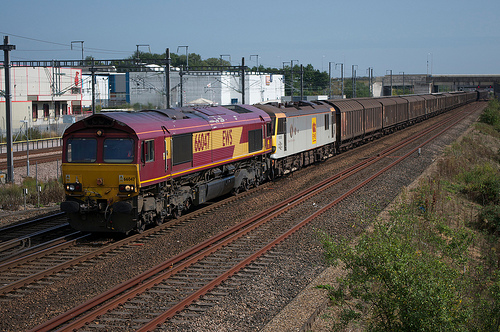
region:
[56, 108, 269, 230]
dark red train engine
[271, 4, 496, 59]
clear afternoon sky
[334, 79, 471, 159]
long line of cargo trains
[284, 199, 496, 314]
foliage bounding the tracks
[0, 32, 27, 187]
telephone poles near the trains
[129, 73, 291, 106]
white buildings in background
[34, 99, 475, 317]
rusty train tracks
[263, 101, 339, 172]
grey secondary train engine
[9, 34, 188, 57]
telephone wires running overhead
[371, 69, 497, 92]
bridge over the tracks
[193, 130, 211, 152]
numbers on the side of a train "66047"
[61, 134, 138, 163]
two train engine windows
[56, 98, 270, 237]
a red and yellow train engine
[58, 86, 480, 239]
a train on the train tracks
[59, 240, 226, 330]
a section of railroad tracks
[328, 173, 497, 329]
bushes on the side of train tracks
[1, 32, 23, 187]
power line pole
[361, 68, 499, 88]
An overpass over train tracks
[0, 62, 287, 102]
two buildings in next to train tracks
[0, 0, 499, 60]
a clear blue sky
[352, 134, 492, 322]
trees near railroad tracks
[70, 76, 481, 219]
long cargo train with many cars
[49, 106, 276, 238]
red first train engine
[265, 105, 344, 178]
grey second train engine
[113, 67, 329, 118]
white buildings in background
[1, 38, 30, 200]
telephone poles with wires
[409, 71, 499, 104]
bridge running over tracks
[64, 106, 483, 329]
rusty well-worn train tracks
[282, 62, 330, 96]
trees away from buildings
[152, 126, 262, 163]
yellow stripe on side of train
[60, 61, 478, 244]
A long train with several cars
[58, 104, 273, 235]
A red and yellow engine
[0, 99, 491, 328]
The train track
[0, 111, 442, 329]
Lots of gravel between the tracks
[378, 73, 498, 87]
A distant overpass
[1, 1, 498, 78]
The sky is clear and blue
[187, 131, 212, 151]
A number in red on the train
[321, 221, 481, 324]
A bush alongside the tracks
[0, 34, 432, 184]
A lot of wooden poles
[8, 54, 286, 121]
Some white buildings behind the train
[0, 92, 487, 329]
two sets of train tracks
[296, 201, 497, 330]
a green plant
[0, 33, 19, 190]
a gray electric pole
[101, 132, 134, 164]
a front window on the train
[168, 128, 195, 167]
a side window on the train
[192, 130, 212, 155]
red writing on the train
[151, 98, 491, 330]
a patch of gravel by the tracks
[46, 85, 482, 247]
a long train